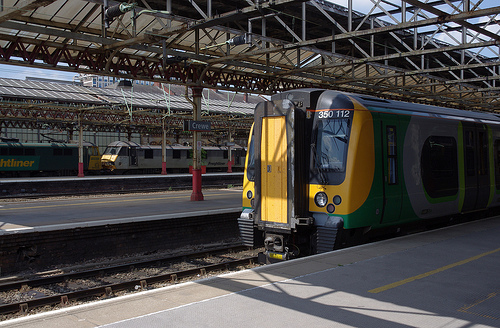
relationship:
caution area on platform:
[0, 217, 484, 327] [208, 271, 397, 323]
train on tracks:
[237, 87, 500, 266] [36, 245, 139, 301]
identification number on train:
[310, 105, 354, 119] [238, 85, 499, 260]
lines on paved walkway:
[362, 254, 499, 311] [0, 189, 497, 328]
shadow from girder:
[195, 216, 500, 328] [120, 4, 498, 94]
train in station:
[238, 85, 499, 260] [1, 0, 495, 326]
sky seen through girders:
[411, 2, 481, 42] [337, 3, 479, 55]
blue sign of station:
[183, 120, 211, 132] [0, 0, 500, 328]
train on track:
[237, 87, 500, 266] [13, 219, 363, 327]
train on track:
[99, 131, 239, 173] [0, 156, 120, 199]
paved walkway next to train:
[6, 210, 498, 325] [238, 85, 499, 260]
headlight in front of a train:
[314, 191, 328, 207] [238, 85, 499, 260]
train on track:
[101, 140, 248, 175] [7, 206, 291, 319]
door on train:
[261, 116, 288, 224] [279, 92, 479, 232]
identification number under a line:
[319, 110, 351, 119] [311, 102, 352, 112]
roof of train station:
[16, 59, 261, 128] [3, 1, 493, 326]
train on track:
[237, 87, 500, 266] [17, 248, 189, 299]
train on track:
[238, 85, 499, 260] [3, 238, 270, 319]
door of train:
[257, 116, 290, 224] [238, 85, 499, 260]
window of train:
[320, 115, 345, 176] [238, 85, 499, 260]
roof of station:
[6, 3, 498, 105] [1, 0, 495, 326]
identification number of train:
[319, 110, 351, 119] [238, 85, 499, 260]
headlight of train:
[312, 191, 327, 208] [238, 85, 499, 260]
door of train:
[261, 116, 288, 224] [191, 89, 495, 264]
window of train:
[415, 119, 466, 206] [238, 85, 499, 260]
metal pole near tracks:
[192, 86, 202, 200] [4, 241, 220, 281]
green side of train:
[350, 106, 499, 233] [238, 85, 499, 260]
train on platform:
[237, 87, 500, 266] [288, 245, 495, 327]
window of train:
[309, 118, 350, 186] [238, 85, 499, 260]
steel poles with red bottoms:
[73, 56, 214, 198] [73, 155, 213, 206]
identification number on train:
[319, 110, 351, 119] [237, 87, 500, 266]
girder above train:
[0, 0, 500, 114] [238, 85, 499, 260]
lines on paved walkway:
[368, 248, 500, 320] [0, 189, 497, 328]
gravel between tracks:
[103, 254, 142, 289] [43, 250, 166, 295]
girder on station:
[0, 0, 500, 114] [34, 7, 481, 312]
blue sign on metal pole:
[177, 116, 228, 134] [189, 85, 204, 201]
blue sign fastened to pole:
[183, 120, 211, 132] [191, 130, 211, 191]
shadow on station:
[217, 227, 495, 327] [0, 0, 500, 328]